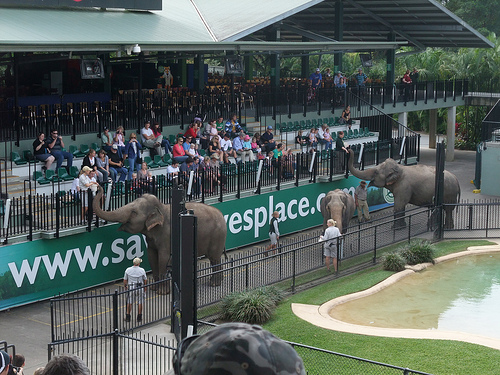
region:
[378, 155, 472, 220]
this is a elephant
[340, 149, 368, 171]
this is the trunk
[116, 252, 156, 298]
this is a man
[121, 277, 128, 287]
the man is light skinned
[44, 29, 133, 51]
this is the roof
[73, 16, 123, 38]
the roof is blue in color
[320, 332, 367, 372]
this is a grass area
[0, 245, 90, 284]
this is a writing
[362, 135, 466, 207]
this is a elephant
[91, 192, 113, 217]
this is the trunk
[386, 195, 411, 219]
this is the leg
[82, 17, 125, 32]
this is the roof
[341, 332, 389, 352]
this is a grass area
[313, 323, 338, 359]
the grass is green in color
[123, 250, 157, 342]
this is a man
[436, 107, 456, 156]
this is a pillar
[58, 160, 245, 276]
elephant interacting with people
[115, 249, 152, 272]
man is wearing a hat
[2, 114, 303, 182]
an audience watching the elephants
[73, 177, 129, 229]
the trunk is long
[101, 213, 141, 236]
the mouth is open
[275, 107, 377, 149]
the seats are green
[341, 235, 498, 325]
the water is calm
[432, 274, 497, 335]
sky reflected in the water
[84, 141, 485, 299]
two gray elephants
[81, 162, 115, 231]
person touching the elephant's trunk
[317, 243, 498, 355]
shallow body of water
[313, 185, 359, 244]
small baby elephant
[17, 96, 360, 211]
spectators in the stands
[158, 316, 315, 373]
top of a hat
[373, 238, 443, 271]
two green bushes by the waterside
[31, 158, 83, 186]
empty green seats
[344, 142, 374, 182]
trunk is lifted up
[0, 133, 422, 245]
black fence along the stands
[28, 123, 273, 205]
people sitting in stands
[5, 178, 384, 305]
white words on a green wall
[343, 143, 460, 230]
elephant reaching up with trunk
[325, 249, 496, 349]
pool of water with reflection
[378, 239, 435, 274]
bushes on side of pool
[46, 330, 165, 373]
poles on black fence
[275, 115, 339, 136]
empty green chairs in arena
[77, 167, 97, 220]
person in front of elephant trunk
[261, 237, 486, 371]
neatly trimmed grass around pool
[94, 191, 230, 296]
elephant standing on a paved surface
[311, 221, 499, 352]
a pool of water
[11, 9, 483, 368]
a scene during the day time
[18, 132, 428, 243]
a black fence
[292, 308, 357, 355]
the pool is tan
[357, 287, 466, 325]
the water is brown and blue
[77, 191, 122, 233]
this is the elephants trunk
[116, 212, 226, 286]
the elephant is gray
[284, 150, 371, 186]
the elephant is reaching for the person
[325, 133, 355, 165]
the person is touching the elephant